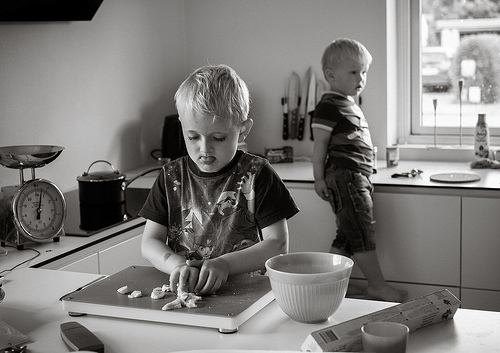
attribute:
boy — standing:
[136, 57, 301, 299]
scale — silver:
[0, 142, 71, 253]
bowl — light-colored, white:
[264, 248, 357, 325]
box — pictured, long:
[298, 283, 465, 352]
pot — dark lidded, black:
[76, 158, 169, 235]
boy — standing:
[303, 35, 412, 305]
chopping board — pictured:
[58, 264, 288, 336]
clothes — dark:
[308, 86, 382, 256]